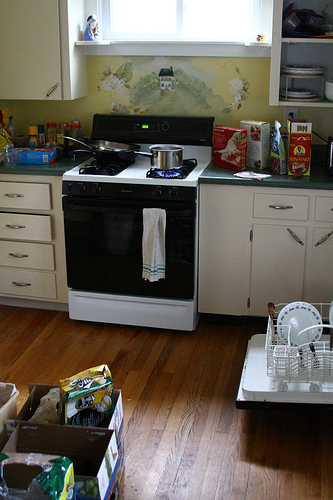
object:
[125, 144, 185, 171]
pot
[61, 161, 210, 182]
stove top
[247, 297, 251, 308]
hinge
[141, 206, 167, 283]
towel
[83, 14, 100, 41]
figurine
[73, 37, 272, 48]
window ledge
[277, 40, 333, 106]
cabinet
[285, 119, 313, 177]
box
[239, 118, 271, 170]
box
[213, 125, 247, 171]
box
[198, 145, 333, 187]
counter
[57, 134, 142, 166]
skillets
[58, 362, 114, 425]
box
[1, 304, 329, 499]
floor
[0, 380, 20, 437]
trash can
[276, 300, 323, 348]
plate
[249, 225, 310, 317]
door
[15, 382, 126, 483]
box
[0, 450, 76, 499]
box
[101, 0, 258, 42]
window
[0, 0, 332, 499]
kitchen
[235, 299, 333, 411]
dish washer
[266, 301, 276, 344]
spoon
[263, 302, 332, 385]
dishwasher rack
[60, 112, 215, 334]
oven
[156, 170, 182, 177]
flame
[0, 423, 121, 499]
box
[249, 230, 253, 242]
hinge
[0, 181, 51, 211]
drawer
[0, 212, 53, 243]
drawer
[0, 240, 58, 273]
drawer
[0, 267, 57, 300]
drawer